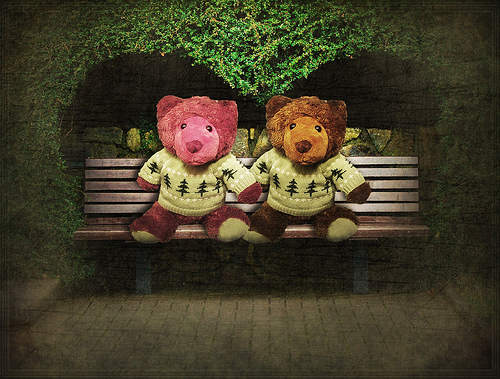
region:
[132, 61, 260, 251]
a pink teddy bear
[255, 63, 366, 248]
a brown teddy bear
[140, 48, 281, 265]
a teddy bear with a sweater on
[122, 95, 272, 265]
trees on a small sweater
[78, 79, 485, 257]
teddy bears sitting on a bench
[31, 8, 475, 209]
a heart shaped bush in the back groung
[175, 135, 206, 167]
teddy bear pink nose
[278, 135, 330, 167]
teddy bear brown nose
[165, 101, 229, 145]
eyes on a teddy bear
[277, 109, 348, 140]
brown teddy bear eyes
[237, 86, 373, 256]
stuffed animal on a bench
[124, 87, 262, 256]
stuffed animal on a bench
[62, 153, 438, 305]
bench made of wood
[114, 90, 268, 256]
stuffed animal wearing a sweater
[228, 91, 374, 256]
stuffed animal wearing a sweater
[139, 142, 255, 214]
small sweater with trees on it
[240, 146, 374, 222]
small sweater with trees on it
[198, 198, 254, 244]
foot of a stuffed animal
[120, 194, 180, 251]
foot of a stuffed animal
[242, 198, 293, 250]
foot of a stuffed animal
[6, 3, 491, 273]
hedge trimmed in a heart shape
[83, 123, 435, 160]
flat stones in wall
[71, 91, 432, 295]
two bears on bench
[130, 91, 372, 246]
two stuffed teddy bears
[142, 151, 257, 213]
white sweater with trees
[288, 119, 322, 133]
two black plastic eyes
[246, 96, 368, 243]
brown bear in sweater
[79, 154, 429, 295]
bench with no arms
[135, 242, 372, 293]
two legs under bench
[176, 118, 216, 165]
pink face on bear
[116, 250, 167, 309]
silver foot on bench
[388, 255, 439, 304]
stone wall behind bench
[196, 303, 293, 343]
brown bricks on the ground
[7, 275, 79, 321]
steps at side of bench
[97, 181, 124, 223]
red color on bench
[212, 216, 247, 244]
white bottom on feet of bear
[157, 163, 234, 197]
christmas tree design on sweater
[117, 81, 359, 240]
bears sitting on bench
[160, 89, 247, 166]
pink color on bear's face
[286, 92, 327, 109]
fur on brown bear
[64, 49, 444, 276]
two bears sitting on a wooden bench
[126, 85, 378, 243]
male and female bears sitting on a wooden bench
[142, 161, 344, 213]
two bears wearing the same sweater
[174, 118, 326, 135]
two bears black eyes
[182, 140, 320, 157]
two bears brown noses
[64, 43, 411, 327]
two bears sitting on a wooden bench with heart shape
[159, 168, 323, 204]
two bears with christmas trees on their sweaters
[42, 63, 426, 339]
two bears sitting on a wooden bench on brick floor